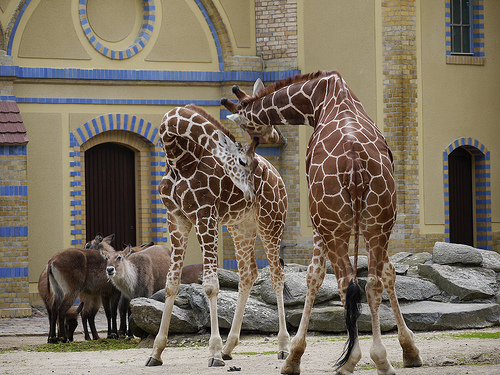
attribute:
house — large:
[15, 6, 486, 277]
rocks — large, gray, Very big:
[135, 239, 498, 336]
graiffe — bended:
[131, 90, 443, 288]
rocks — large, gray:
[388, 257, 495, 322]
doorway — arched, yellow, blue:
[79, 144, 159, 269]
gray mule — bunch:
[96, 240, 174, 327]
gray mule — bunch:
[35, 247, 114, 341]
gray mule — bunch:
[101, 241, 143, 253]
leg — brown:
[319, 229, 356, 331]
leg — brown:
[353, 233, 386, 352]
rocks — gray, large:
[140, 254, 498, 334]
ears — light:
[226, 79, 262, 124]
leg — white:
[145, 210, 191, 366]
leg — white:
[194, 215, 225, 365]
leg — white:
[221, 212, 257, 358]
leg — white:
[255, 202, 291, 359]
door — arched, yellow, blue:
[76, 133, 166, 240]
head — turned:
[202, 115, 261, 212]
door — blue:
[74, 119, 216, 260]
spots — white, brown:
[334, 121, 405, 225]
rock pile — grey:
[133, 237, 498, 336]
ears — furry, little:
[96, 241, 131, 255]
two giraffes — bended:
[146, 71, 437, 373]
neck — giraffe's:
[271, 76, 323, 128]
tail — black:
[332, 166, 364, 373]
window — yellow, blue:
[437, 3, 499, 93]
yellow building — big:
[1, 4, 152, 224]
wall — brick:
[0, 140, 30, 318]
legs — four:
[165, 210, 290, 350]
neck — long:
[163, 113, 232, 159]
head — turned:
[209, 119, 258, 211]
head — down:
[228, 81, 271, 205]